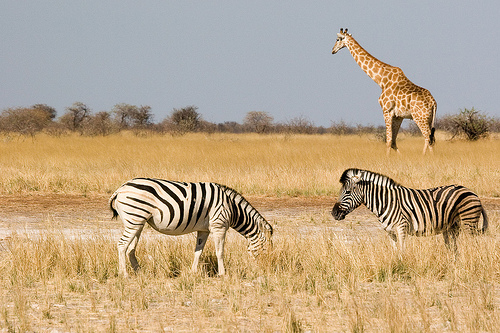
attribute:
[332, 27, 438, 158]
giraffe — tall, here, standing, brown, white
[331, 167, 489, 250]
zebra — eating, here, black, white, standing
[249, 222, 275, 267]
head — down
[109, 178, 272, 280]
zebra — grazing, bent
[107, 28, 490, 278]
animals — three, standing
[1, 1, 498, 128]
sky — hazy, gray, blue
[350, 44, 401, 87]
neck — long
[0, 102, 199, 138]
trees — distant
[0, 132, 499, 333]
plain — here, yellow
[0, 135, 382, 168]
grass — here, yellow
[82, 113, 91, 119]
branch — here